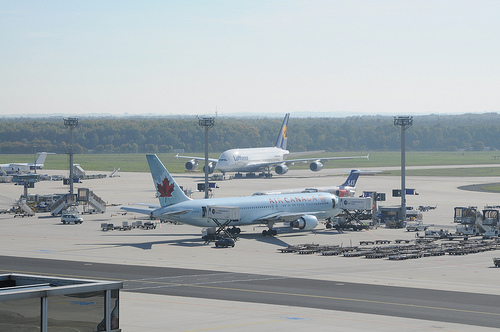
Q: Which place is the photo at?
A: It is at the airport.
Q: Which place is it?
A: It is an airport.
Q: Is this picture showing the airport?
A: Yes, it is showing the airport.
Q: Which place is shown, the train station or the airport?
A: It is the airport.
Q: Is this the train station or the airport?
A: It is the airport.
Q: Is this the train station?
A: No, it is the airport.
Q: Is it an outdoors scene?
A: Yes, it is outdoors.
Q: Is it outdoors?
A: Yes, it is outdoors.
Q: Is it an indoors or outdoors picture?
A: It is outdoors.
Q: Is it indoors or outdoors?
A: It is outdoors.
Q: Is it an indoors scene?
A: No, it is outdoors.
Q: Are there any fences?
A: No, there are no fences.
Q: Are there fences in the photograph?
A: No, there are no fences.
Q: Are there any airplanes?
A: Yes, there is an airplane.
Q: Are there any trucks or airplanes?
A: Yes, there is an airplane.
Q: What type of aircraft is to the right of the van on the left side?
A: The aircraft is an airplane.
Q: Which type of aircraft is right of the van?
A: The aircraft is an airplane.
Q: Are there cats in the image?
A: No, there are no cats.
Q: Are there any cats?
A: No, there are no cats.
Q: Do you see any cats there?
A: No, there are no cats.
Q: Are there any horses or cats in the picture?
A: No, there are no cats or horses.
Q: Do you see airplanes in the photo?
A: Yes, there is an airplane.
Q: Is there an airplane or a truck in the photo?
A: Yes, there is an airplane.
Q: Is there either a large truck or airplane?
A: Yes, there is a large airplane.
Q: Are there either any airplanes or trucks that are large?
A: Yes, the airplane is large.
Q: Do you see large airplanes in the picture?
A: Yes, there is a large airplane.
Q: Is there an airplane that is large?
A: Yes, there is an airplane that is large.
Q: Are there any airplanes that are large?
A: Yes, there is an airplane that is large.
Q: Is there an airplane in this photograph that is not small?
A: Yes, there is a large airplane.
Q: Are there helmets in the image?
A: No, there are no helmets.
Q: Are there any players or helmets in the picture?
A: No, there are no helmets or players.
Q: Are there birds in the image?
A: No, there are no birds.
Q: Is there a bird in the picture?
A: No, there are no birds.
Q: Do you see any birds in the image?
A: No, there are no birds.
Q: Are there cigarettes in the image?
A: No, there are no cigarettes.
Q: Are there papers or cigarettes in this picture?
A: No, there are no cigarettes or papers.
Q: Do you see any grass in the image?
A: Yes, there is grass.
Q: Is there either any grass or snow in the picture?
A: Yes, there is grass.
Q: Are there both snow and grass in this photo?
A: No, there is grass but no snow.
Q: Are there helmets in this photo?
A: No, there are no helmets.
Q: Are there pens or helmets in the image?
A: No, there are no helmets or pens.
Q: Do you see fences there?
A: No, there are no fences.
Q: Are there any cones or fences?
A: No, there are no fences or cones.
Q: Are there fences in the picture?
A: No, there are no fences.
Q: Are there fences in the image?
A: No, there are no fences.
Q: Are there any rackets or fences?
A: No, there are no fences or rackets.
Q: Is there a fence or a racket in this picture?
A: No, there are no fences or rackets.